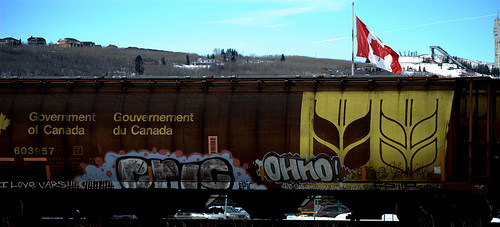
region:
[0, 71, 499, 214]
brown and yellow train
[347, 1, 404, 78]
red and white canadian flag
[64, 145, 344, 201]
white and black graffiti on the train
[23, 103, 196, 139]
yellow letters on the brown train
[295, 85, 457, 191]
yellow picture on the train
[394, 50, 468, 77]
snow on the mountain in the background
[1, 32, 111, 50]
ancient buildings in the background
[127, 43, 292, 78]
trees on the hillside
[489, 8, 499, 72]
gray tower to the right of the photo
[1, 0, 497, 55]
very blue sky above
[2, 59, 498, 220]
freight train on tracks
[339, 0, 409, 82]
canadian flag on pole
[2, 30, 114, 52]
buildings on top of hill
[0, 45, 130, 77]
hill behind the train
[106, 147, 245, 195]
graffiti on a train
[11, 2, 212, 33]
blue sky in the distance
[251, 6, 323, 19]
clouds in the sky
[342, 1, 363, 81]
pole for a flag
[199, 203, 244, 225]
car parked behind train tracks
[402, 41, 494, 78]
snow and slope in the background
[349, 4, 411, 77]
Canadian flag blowing in breeze.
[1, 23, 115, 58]
Buildings on a hill over looking field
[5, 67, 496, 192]
Brown and yellow box car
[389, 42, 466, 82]
Snow on hill side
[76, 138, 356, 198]
Graffiti on side of box car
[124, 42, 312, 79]
Trees on hillside with snow.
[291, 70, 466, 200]
Image of wheat on side of train car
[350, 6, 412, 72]
Maple leaf on flag.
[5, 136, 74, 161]
Numbers on side of train car.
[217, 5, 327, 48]
Cloud in blue sky.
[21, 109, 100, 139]
yellow printed words Government of Canada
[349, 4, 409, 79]
a waving red and white Canadian flag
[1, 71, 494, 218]
a brown train car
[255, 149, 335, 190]
spray painted grafitti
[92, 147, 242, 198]
spray painted grafitti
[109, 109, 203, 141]
yellow printed words Gouvernement du Canada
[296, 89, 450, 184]
a yellow printed logo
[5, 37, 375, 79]
a hillside in distance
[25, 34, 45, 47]
house at top of hill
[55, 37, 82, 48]
house at top of hill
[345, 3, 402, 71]
red and white flag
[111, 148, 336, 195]
spray paint on train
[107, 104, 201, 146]
yellow words on side of train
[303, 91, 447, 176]
illustration on side of train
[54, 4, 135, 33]
blue of daytime sky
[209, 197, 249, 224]
parked car beyond tracks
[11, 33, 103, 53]
buildings on hillside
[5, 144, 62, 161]
number on side of train